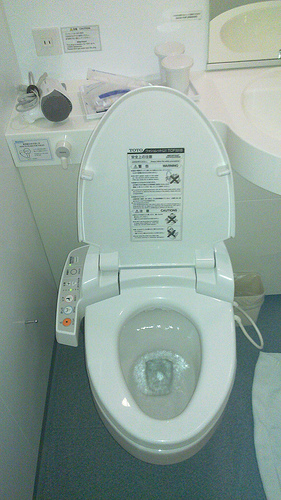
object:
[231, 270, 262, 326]
trash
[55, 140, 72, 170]
handle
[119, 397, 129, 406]
light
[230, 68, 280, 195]
sink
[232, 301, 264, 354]
tubing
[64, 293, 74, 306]
buttons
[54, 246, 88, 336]
side display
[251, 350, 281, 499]
towel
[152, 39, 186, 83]
cup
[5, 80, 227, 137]
shelf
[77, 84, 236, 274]
toilet lid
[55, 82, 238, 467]
white toilet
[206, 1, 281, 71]
mirror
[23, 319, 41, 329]
hanger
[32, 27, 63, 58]
outlet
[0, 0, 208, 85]
wall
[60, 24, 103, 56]
sign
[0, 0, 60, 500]
wall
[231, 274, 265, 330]
trash can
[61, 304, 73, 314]
button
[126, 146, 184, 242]
display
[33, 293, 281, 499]
floor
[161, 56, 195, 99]
container